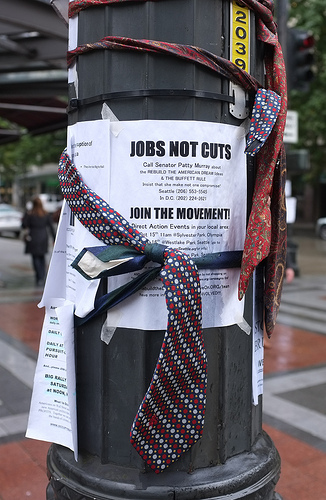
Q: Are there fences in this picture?
A: No, there are no fences.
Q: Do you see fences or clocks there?
A: No, there are no fences or clocks.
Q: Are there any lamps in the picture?
A: No, there are no lamps.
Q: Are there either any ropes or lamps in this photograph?
A: No, there are no lamps or ropes.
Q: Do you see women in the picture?
A: Yes, there is a woman.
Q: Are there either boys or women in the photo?
A: Yes, there is a woman.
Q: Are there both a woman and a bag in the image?
A: No, there is a woman but no bags.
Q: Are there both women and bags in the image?
A: No, there is a woman but no bags.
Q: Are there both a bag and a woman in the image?
A: No, there is a woman but no bags.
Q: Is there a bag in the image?
A: No, there are no bags.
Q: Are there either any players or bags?
A: No, there are no bags or players.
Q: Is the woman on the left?
A: Yes, the woman is on the left of the image.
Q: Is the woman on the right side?
A: No, the woman is on the left of the image.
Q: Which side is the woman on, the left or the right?
A: The woman is on the left of the image.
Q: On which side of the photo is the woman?
A: The woman is on the left of the image.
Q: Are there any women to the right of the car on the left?
A: Yes, there is a woman to the right of the car.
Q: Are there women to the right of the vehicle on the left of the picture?
A: Yes, there is a woman to the right of the car.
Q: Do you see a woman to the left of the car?
A: No, the woman is to the right of the car.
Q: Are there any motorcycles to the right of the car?
A: No, there is a woman to the right of the car.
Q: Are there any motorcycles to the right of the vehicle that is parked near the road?
A: No, there is a woman to the right of the car.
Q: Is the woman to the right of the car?
A: Yes, the woman is to the right of the car.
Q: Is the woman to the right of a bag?
A: No, the woman is to the right of the car.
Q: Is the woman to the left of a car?
A: No, the woman is to the right of a car.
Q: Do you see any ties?
A: Yes, there is a tie.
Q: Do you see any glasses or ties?
A: Yes, there is a tie.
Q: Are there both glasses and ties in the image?
A: No, there is a tie but no glasses.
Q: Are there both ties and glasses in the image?
A: No, there is a tie but no glasses.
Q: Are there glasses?
A: No, there are no glasses.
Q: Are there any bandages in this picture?
A: No, there are no bandages.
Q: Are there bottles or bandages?
A: No, there are no bandages or bottles.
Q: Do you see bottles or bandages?
A: No, there are no bandages or bottles.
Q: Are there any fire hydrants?
A: No, there are no fire hydrants.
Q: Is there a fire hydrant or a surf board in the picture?
A: No, there are no fire hydrants or surfboards.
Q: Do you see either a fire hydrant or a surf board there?
A: No, there are no fire hydrants or surfboards.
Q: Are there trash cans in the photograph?
A: No, there are no trash cans.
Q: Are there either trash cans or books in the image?
A: No, there are no trash cans or books.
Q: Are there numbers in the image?
A: Yes, there are numbers.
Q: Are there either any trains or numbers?
A: Yes, there are numbers.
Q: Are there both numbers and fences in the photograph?
A: No, there are numbers but no fences.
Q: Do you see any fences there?
A: No, there are no fences.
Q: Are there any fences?
A: No, there are no fences.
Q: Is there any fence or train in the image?
A: No, there are no fences or trains.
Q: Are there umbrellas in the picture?
A: No, there are no umbrellas.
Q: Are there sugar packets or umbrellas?
A: No, there are no umbrellas or sugar packets.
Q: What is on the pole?
A: The paper is on the pole.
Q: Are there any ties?
A: Yes, there is a tie.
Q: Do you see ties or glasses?
A: Yes, there is a tie.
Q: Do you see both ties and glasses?
A: No, there is a tie but no glasses.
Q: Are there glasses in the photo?
A: No, there are no glasses.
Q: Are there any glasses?
A: No, there are no glasses.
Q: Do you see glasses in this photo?
A: No, there are no glasses.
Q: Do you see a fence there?
A: No, there are no fences.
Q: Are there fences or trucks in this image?
A: No, there are no fences or trucks.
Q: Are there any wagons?
A: No, there are no wagons.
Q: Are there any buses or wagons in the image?
A: No, there are no wagons or buses.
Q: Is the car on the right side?
A: No, the car is on the left of the image.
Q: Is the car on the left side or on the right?
A: The car is on the left of the image.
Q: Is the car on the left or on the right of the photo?
A: The car is on the left of the image.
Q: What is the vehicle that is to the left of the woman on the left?
A: The vehicle is a car.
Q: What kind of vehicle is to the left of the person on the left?
A: The vehicle is a car.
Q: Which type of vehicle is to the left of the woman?
A: The vehicle is a car.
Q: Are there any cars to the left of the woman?
A: Yes, there is a car to the left of the woman.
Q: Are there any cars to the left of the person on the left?
A: Yes, there is a car to the left of the woman.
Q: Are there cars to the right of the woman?
A: No, the car is to the left of the woman.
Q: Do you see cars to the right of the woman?
A: No, the car is to the left of the woman.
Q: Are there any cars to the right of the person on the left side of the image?
A: No, the car is to the left of the woman.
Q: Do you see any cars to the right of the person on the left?
A: No, the car is to the left of the woman.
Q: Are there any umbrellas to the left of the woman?
A: No, there is a car to the left of the woman.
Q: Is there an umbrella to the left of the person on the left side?
A: No, there is a car to the left of the woman.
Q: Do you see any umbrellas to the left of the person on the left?
A: No, there is a car to the left of the woman.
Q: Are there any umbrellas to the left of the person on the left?
A: No, there is a car to the left of the woman.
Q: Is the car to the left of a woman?
A: Yes, the car is to the left of a woman.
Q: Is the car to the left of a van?
A: No, the car is to the left of a woman.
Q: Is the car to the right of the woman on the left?
A: No, the car is to the left of the woman.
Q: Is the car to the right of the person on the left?
A: No, the car is to the left of the woman.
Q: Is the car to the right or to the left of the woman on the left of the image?
A: The car is to the left of the woman.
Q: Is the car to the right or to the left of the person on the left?
A: The car is to the left of the woman.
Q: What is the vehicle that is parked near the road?
A: The vehicle is a car.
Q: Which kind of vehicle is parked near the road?
A: The vehicle is a car.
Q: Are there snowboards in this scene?
A: No, there are no snowboards.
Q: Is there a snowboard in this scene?
A: No, there are no snowboards.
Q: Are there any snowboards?
A: No, there are no snowboards.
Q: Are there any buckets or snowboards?
A: No, there are no snowboards or buckets.